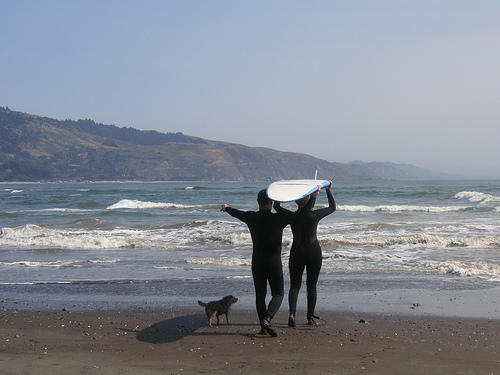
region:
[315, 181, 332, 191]
Two people carrying a board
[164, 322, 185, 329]
Shadow of the surf board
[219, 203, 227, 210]
Hand is held out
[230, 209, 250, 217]
Arm is stretched out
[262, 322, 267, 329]
Sole of foot raised up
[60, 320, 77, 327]
Pebbles on the beach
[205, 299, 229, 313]
A black dog on the beach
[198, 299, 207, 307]
Tail of dog raised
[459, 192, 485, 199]
A wave in the rushing in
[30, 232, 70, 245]
Waves breaking ashore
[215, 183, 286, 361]
PErson wearing a black wet suite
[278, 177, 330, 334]
PErson wearing a black wet suite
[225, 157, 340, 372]
People carrying a blue and white surfboard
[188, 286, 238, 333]
Small brown dog iin the samd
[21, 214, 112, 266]
Small wave in the water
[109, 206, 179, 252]
Small wave in the water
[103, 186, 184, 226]
Small wave in the water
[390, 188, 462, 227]
Small wave in the water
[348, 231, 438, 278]
Small wave in the water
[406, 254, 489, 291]
Small wave in the water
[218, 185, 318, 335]
A person in a wet suit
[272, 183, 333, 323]
A person in a wet suit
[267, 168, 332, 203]
A blue and white surfboard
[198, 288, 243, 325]
A small dog on the beach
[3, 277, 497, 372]
A wet sandy beach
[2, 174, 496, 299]
The ocean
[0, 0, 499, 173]
A clear blue sky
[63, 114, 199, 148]
A large forested area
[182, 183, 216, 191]
A small wave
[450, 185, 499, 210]
A large wave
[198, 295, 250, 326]
small dog on beach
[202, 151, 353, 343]
surfers carrying white surf board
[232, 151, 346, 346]
surfers wearing black wet suits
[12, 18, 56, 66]
white clouds in blue sky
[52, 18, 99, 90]
white clouds in blue sky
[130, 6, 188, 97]
white clouds in blue sky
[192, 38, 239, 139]
white clouds in blue sky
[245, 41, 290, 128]
white clouds in blue sky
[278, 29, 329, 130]
white clouds in blue sky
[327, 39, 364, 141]
white clouds in blue sky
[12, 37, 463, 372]
People and dog at ocean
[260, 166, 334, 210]
Blue and white surfboard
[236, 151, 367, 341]
Two people carrying surfboard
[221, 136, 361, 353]
Two people approaching ocean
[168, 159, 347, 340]
Two people and a dog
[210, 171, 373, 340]
Two people wearing wetsuits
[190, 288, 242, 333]
Dog walking on sand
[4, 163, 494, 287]
Small waves on ocean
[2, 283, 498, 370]
Brown rock strewn beach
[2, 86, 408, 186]
Brown and green hills